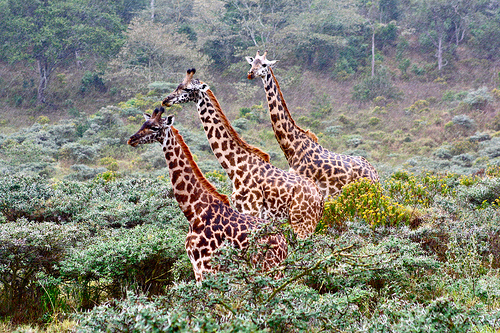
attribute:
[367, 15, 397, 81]
tree — many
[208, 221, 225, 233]
shape — brown, cream color, polygon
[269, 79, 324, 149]
mane — brown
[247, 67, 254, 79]
nose — brown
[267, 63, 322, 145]
mane — brown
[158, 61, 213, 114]
head — small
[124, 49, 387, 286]
giraffes — three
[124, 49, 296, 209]
neck — long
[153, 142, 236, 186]
hair — brown